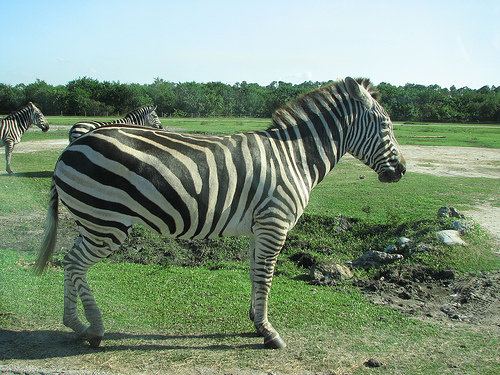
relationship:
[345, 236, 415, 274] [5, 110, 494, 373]
rock on ground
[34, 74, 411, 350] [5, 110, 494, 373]
zebra on ground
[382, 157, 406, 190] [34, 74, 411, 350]
nose on zebra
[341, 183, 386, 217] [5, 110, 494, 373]
grass covering ground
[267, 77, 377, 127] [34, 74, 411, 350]
mane on zebra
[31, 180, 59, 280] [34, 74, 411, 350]
tail on zebra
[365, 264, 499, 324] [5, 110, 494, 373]
dirt on ground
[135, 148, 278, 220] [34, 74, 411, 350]
stripes on zebra